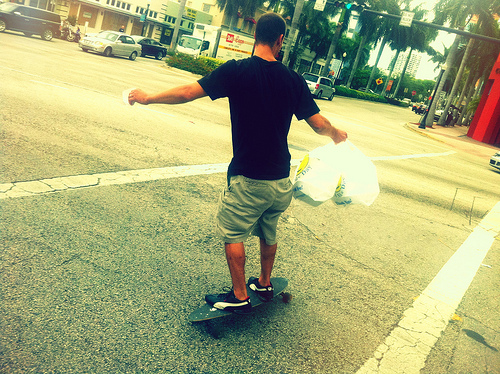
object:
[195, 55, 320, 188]
black shirt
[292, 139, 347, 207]
decal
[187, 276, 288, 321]
couch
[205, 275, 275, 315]
shoes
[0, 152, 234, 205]
white line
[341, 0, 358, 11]
traffic light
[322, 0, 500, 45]
pole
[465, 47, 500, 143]
structure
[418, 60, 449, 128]
street light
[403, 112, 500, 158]
corner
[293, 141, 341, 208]
bags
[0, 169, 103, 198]
cracks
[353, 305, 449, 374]
cracks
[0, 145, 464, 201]
white paint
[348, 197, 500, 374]
white paint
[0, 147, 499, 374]
crosswalk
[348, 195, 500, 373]
lines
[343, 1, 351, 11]
green color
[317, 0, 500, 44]
traffic post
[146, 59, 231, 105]
arms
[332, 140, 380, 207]
bag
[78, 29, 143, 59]
car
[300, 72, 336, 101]
car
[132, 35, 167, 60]
car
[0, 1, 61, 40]
car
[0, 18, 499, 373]
street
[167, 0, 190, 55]
pole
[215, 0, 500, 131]
trees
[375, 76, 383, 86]
sign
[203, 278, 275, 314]
feet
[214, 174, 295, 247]
pants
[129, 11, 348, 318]
he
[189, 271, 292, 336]
skateboard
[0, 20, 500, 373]
road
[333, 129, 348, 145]
hand